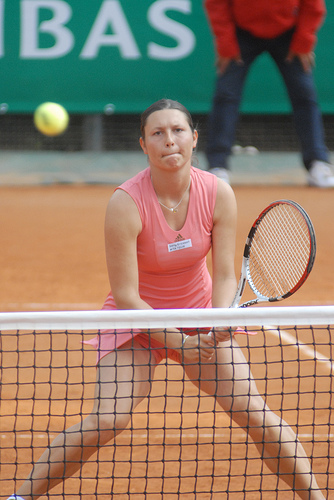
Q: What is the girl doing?
A: Playing tennis.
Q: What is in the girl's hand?
A: A tennis racket.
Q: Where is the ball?
A: Above the net.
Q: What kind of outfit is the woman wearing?
A: Pink tennis uniform.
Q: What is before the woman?
A: A net.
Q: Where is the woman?
A: On a tennis court.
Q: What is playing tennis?
A: The woman.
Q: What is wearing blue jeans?
A: The person.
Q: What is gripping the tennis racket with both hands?
A: The woman.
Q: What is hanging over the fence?
A: Green tarp.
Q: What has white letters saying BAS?
A: The green tarp.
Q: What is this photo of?
A: A court.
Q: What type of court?
A: Tennis.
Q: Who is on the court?
A: A woman.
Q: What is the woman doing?
A: Playing tennis.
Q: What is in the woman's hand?
A: A racket.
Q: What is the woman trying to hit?
A: A ball.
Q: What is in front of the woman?
A: A net.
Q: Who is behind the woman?
A: A man.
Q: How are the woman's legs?
A: Spread apart.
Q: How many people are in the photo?
A: Two.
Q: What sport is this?
A: Tennis.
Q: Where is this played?
A: Tennis court.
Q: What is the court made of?
A: Clay.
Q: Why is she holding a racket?
A: Hit the ball.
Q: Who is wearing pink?
A: Lady.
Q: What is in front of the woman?
A: Net.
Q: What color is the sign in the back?
A: Green.